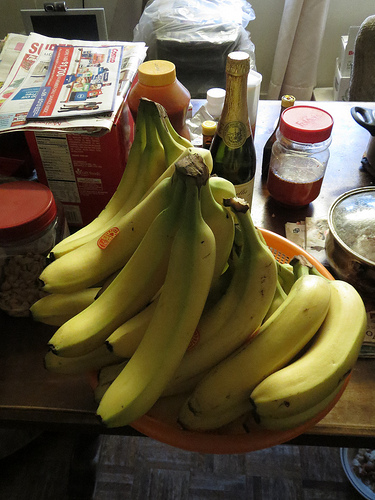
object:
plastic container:
[0, 178, 72, 325]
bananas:
[47, 188, 188, 360]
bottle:
[208, 49, 256, 214]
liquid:
[264, 152, 325, 207]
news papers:
[0, 31, 150, 137]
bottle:
[125, 58, 191, 148]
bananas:
[248, 261, 368, 419]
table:
[0, 98, 374, 451]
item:
[264, 104, 333, 208]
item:
[259, 95, 296, 187]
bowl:
[82, 223, 353, 454]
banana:
[186, 256, 331, 418]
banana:
[49, 108, 167, 261]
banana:
[103, 178, 235, 358]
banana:
[34, 169, 176, 295]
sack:
[131, 0, 257, 96]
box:
[23, 66, 141, 234]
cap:
[278, 103, 333, 145]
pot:
[323, 183, 374, 295]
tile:
[91, 470, 134, 499]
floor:
[87, 432, 362, 498]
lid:
[135, 60, 178, 89]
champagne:
[207, 129, 256, 210]